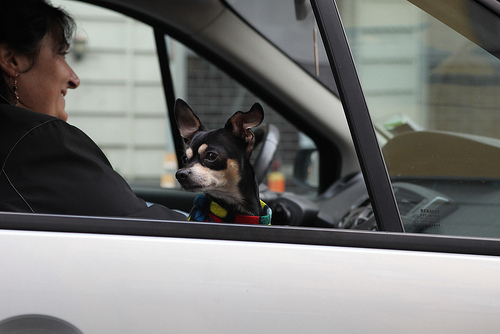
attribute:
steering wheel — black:
[247, 120, 281, 185]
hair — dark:
[3, 3, 76, 113]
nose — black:
[173, 170, 190, 182]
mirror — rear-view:
[287, 4, 314, 25]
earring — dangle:
[9, 54, 28, 104]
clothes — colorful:
[207, 198, 271, 222]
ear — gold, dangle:
[220, 79, 275, 158]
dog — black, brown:
[166, 100, 269, 225]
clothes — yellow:
[183, 190, 272, 223]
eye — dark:
[202, 148, 217, 162]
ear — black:
[170, 97, 210, 148]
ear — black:
[223, 102, 264, 149]